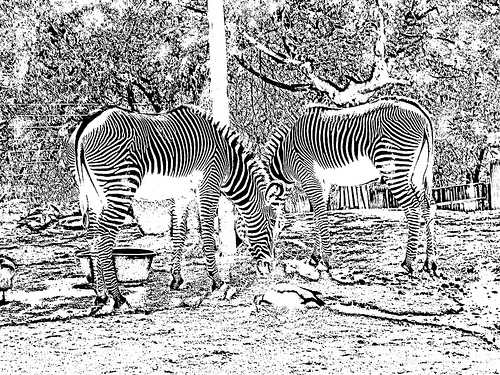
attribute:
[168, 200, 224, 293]
feet — apart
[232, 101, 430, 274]
zebra — black and white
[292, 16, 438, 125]
trees — tall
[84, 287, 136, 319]
hooves — black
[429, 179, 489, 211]
fence — wooden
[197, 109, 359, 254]
zebra — striped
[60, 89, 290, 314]
zebra — standing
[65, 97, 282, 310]
zebra — grazing, black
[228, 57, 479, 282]
zebra — bent down, eating